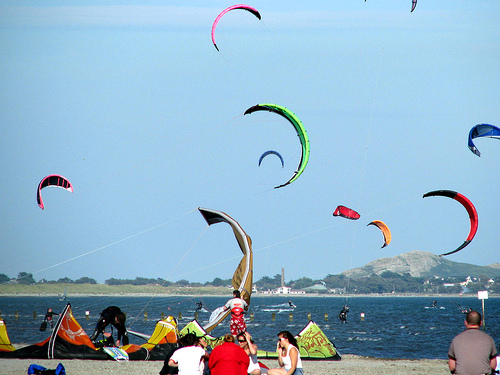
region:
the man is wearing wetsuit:
[87, 293, 150, 360]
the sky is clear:
[100, 42, 344, 209]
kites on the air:
[38, 35, 439, 315]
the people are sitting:
[137, 320, 323, 372]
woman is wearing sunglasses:
[264, 332, 305, 354]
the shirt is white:
[271, 345, 313, 367]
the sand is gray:
[322, 352, 382, 372]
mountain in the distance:
[160, 247, 474, 303]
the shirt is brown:
[438, 325, 496, 372]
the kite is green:
[225, 83, 340, 210]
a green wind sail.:
[239, 91, 341, 214]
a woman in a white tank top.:
[266, 321, 303, 373]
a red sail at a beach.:
[47, 294, 100, 360]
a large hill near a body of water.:
[303, 248, 497, 288]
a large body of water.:
[0, 299, 498, 349]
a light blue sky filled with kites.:
[3, 3, 498, 284]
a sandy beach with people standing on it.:
[3, 346, 497, 372]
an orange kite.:
[363, 219, 401, 264]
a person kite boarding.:
[335, 303, 360, 324]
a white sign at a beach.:
[460, 289, 492, 319]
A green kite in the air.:
[217, 85, 314, 196]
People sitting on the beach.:
[161, 318, 312, 373]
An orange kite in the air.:
[361, 213, 402, 258]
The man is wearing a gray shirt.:
[441, 308, 496, 373]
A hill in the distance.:
[317, 223, 487, 295]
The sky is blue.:
[30, 45, 165, 135]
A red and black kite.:
[406, 170, 486, 282]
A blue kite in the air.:
[453, 98, 498, 158]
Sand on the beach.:
[320, 360, 401, 371]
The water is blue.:
[360, 295, 422, 326]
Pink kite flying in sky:
[208, 2, 273, 57]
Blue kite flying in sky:
[249, 137, 286, 171]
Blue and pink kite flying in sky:
[27, 157, 77, 211]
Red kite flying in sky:
[324, 200, 360, 229]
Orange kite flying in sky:
[368, 217, 397, 250]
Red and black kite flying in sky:
[417, 182, 477, 264]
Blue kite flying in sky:
[458, 118, 499, 160]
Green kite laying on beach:
[283, 310, 340, 365]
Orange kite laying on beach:
[38, 300, 95, 359]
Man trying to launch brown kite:
[189, 200, 269, 309]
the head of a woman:
[274, 326, 299, 347]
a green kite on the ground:
[251, 313, 344, 360]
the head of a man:
[462, 302, 487, 332]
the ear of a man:
[460, 314, 470, 327]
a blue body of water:
[0, 291, 497, 345]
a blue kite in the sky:
[251, 142, 289, 168]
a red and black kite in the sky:
[416, 181, 479, 263]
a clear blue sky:
[1, 1, 499, 286]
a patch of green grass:
[1, 277, 203, 298]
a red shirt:
[203, 340, 253, 373]